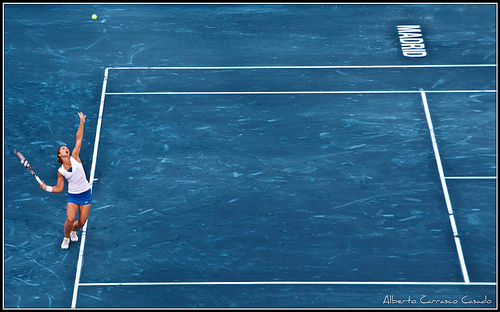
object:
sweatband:
[45, 186, 53, 193]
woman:
[12, 111, 97, 250]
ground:
[216, 140, 344, 225]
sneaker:
[70, 231, 79, 243]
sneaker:
[61, 236, 71, 249]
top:
[58, 156, 91, 194]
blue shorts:
[66, 188, 93, 205]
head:
[57, 146, 70, 160]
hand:
[78, 112, 87, 123]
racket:
[13, 149, 46, 188]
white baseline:
[70, 67, 118, 308]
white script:
[381, 294, 492, 305]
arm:
[71, 123, 87, 156]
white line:
[107, 64, 498, 70]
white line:
[416, 89, 471, 282]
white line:
[106, 89, 499, 95]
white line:
[79, 279, 496, 288]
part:
[54, 148, 61, 153]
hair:
[57, 147, 62, 164]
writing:
[396, 25, 427, 59]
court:
[71, 63, 500, 307]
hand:
[39, 181, 47, 190]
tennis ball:
[91, 14, 97, 20]